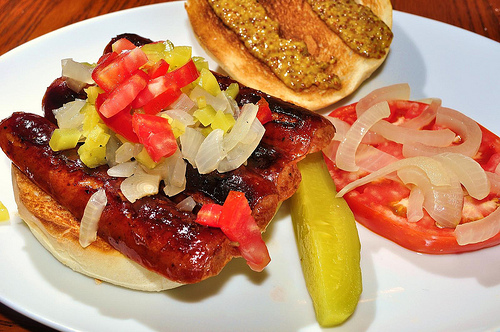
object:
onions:
[334, 101, 392, 172]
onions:
[191, 125, 228, 174]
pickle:
[287, 147, 368, 331]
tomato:
[321, 93, 500, 256]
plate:
[0, 0, 498, 329]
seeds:
[317, 217, 332, 227]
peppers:
[76, 141, 108, 168]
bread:
[183, 0, 395, 112]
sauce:
[210, 0, 394, 90]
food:
[0, 0, 498, 329]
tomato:
[90, 45, 150, 92]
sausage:
[0, 110, 238, 286]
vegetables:
[83, 65, 192, 154]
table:
[0, 1, 498, 328]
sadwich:
[0, 34, 340, 295]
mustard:
[243, 17, 265, 32]